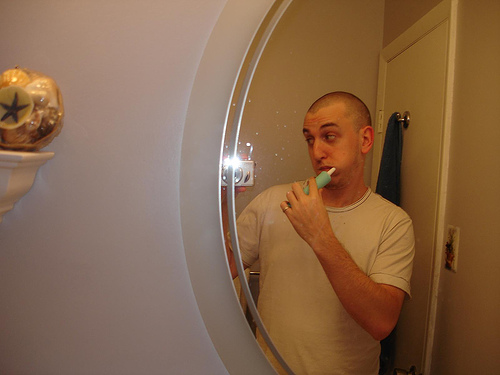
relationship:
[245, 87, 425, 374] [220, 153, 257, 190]
man holding camera